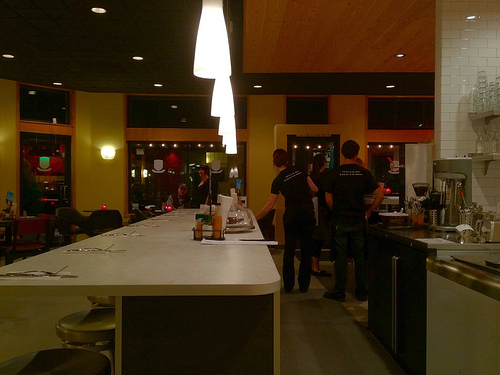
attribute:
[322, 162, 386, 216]
shirt — black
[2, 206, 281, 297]
countertop — long, white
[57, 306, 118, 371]
bar stool — round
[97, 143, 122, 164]
light — bright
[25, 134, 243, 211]
windows — large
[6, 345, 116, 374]
bar stool — silver, metal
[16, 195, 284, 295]
counter — long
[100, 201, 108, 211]
candle — red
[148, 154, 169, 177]
design — coffee cup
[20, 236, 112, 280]
napkins — white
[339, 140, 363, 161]
hair — short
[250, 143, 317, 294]
woman — leaning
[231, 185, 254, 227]
cups — glass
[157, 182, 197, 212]
man — sitting